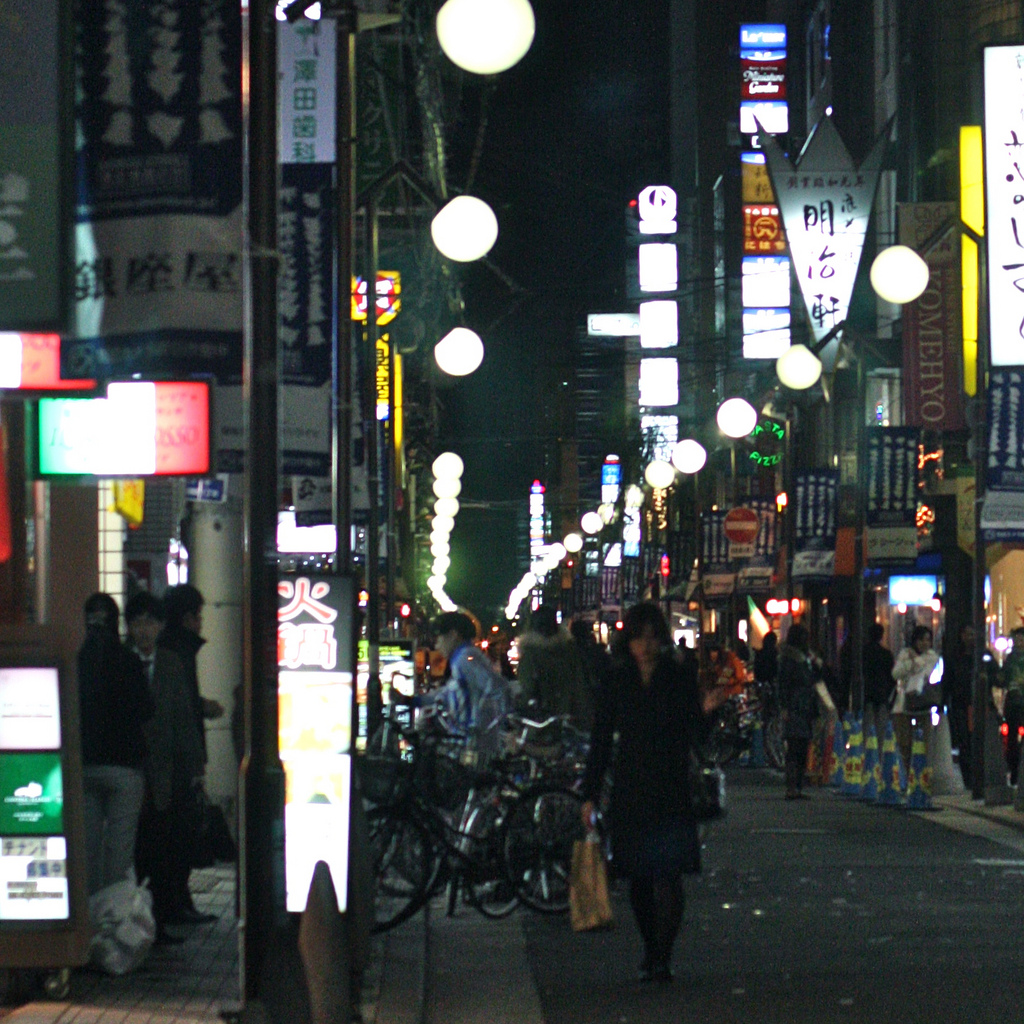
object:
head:
[619, 603, 673, 664]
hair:
[618, 603, 673, 655]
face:
[630, 625, 662, 660]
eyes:
[632, 632, 640, 639]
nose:
[639, 638, 650, 648]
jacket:
[577, 636, 716, 881]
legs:
[618, 876, 698, 964]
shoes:
[633, 961, 658, 984]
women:
[580, 600, 697, 981]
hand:
[578, 794, 597, 833]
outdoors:
[91, 189, 961, 644]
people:
[778, 621, 826, 793]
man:
[427, 608, 510, 768]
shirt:
[430, 647, 501, 748]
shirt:
[890, 647, 939, 704]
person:
[894, 628, 938, 717]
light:
[431, 0, 543, 74]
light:
[430, 195, 499, 263]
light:
[435, 328, 483, 374]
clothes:
[584, 651, 716, 897]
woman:
[577, 587, 722, 987]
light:
[774, 341, 824, 395]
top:
[884, 636, 947, 712]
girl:
[894, 623, 947, 793]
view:
[25, 24, 998, 1011]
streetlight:
[715, 395, 769, 441]